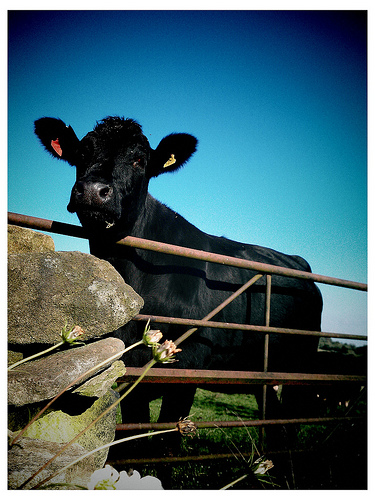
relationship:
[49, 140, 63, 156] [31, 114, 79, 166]
red tag in cow's ear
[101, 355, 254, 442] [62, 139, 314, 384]
legs of cow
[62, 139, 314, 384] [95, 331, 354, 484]
cow in field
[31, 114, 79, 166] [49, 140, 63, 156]
cow's ear with red tag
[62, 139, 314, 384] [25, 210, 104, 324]
cow near fence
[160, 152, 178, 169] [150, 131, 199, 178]
tag attached to ear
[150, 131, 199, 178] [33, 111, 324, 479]
ear belonging to cow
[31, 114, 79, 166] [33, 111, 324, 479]
cow's ear belonging to cow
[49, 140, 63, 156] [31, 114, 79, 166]
red tag attached to cow's ear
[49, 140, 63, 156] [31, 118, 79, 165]
red tag in cow's ear